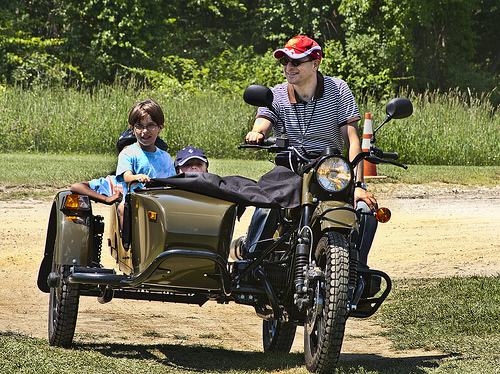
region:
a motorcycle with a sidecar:
[29, 23, 438, 372]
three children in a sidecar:
[37, 97, 221, 359]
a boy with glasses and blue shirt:
[115, 96, 175, 198]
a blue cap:
[170, 139, 208, 171]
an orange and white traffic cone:
[344, 97, 386, 194]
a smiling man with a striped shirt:
[243, 22, 365, 368]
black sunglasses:
[272, 51, 320, 71]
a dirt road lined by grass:
[8, 156, 492, 353]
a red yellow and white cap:
[263, 32, 329, 62]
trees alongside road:
[0, 4, 483, 87]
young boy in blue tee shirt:
[123, 96, 175, 201]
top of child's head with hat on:
[176, 141, 219, 187]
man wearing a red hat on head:
[259, 28, 374, 185]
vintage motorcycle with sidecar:
[57, 111, 428, 371]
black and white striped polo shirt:
[251, 60, 387, 177]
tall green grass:
[17, 87, 421, 149]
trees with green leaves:
[24, 11, 449, 65]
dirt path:
[4, 199, 61, 324]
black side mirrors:
[241, 82, 432, 124]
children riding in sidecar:
[94, 79, 231, 286]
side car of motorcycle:
[37, 182, 279, 348]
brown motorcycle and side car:
[36, 145, 443, 369]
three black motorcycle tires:
[41, 204, 358, 367]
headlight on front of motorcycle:
[312, 151, 359, 201]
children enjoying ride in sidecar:
[66, 97, 231, 212]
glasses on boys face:
[129, 118, 161, 130]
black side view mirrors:
[241, 82, 416, 118]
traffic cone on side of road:
[352, 109, 392, 184]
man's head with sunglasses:
[272, 35, 323, 83]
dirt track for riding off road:
[3, 177, 498, 334]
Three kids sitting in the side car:
[12, 58, 250, 348]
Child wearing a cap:
[176, 136, 231, 241]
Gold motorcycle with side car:
[33, 10, 472, 370]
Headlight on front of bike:
[294, 126, 385, 248]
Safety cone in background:
[343, 88, 408, 215]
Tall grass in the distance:
[13, 30, 498, 192]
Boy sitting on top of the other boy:
[54, 96, 211, 266]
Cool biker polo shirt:
[232, 24, 384, 260]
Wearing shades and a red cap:
[237, 16, 367, 107]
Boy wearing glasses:
[113, 82, 187, 172]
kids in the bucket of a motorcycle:
[61, 72, 241, 292]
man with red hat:
[260, 20, 342, 105]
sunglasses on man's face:
[273, 55, 323, 67]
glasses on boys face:
[91, 100, 163, 144]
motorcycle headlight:
[294, 140, 358, 211]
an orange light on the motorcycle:
[366, 182, 402, 236]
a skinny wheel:
[31, 220, 103, 365]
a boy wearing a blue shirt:
[111, 85, 203, 207]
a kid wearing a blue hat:
[176, 125, 210, 235]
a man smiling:
[206, 28, 366, 151]